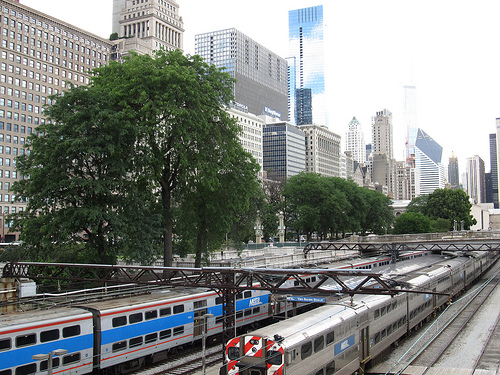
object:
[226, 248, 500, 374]
train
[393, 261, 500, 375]
tracks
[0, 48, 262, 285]
tree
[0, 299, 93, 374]
cars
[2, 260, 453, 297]
supports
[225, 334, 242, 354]
stripes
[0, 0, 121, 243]
buildings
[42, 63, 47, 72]
windows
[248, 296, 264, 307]
logo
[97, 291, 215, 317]
line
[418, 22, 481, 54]
clouds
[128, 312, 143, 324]
windows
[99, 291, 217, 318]
stripe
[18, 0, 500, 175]
sky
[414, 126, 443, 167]
roof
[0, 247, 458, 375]
trains